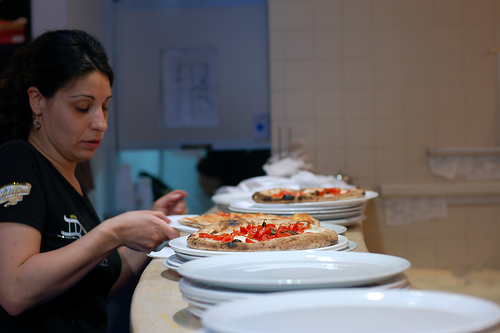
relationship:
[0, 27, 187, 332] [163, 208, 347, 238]
girl holding plate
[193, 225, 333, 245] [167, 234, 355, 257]
pizza on a plate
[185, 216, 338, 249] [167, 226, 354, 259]
pizza on a white plate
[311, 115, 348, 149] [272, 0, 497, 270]
tile on wall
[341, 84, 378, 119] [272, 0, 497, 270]
tile on wall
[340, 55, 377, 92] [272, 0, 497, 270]
tile on wall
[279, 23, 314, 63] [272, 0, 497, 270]
tile on wall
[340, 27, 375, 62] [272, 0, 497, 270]
tile on wall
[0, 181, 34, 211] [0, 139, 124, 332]
logo on shirt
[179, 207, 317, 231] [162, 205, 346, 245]
food on plate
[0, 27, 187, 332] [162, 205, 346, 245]
girl grabbing a plate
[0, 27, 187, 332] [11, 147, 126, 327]
girl wearing a black shirt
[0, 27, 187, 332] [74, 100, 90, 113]
girl closing her eye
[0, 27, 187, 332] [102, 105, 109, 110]
girl closing her eye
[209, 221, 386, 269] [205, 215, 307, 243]
toppings on pizza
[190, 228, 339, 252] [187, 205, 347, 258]
crust on pizza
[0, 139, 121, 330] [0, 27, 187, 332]
shirt on girl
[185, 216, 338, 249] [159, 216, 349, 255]
pizza on plate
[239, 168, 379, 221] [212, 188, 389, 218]
pizza on plate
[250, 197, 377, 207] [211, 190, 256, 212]
plate in a stack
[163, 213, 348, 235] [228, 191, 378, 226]
plate in a stack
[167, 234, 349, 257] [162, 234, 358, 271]
plate in a stack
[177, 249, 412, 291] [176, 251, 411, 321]
plate in a stack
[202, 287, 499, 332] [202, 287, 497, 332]
plate in a stack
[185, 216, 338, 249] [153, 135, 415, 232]
pizza on plates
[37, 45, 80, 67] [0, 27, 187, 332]
hair on girl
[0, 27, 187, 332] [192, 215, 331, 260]
girl getting pizza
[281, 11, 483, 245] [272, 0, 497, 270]
tile on wall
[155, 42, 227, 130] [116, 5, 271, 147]
paper on cabinet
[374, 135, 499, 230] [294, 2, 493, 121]
restaurant orders on wall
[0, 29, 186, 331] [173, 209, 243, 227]
girl taking pizza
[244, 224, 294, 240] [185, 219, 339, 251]
tomatoes are on pizza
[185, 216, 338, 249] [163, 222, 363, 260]
pizza on plate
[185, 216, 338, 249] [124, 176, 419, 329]
pizza on counter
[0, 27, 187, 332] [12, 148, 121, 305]
girl wearing shirt